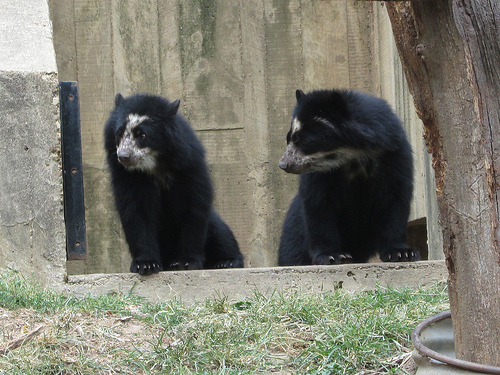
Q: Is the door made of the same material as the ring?
A: No, the door is made of wood and the ring is made of metal.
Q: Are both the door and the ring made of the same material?
A: No, the door is made of wood and the ring is made of metal.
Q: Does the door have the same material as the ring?
A: No, the door is made of wood and the ring is made of metal.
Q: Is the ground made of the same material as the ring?
A: No, the ground is made of concrete and the ring is made of metal.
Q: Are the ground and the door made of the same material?
A: No, the ground is made of cement and the door is made of wood.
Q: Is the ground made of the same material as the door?
A: No, the ground is made of cement and the door is made of wood.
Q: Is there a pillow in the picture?
A: No, there are no pillows.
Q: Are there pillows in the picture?
A: No, there are no pillows.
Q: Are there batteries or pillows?
A: No, there are no pillows or batteries.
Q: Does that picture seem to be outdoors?
A: Yes, the picture is outdoors.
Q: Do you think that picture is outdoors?
A: Yes, the picture is outdoors.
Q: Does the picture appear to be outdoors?
A: Yes, the picture is outdoors.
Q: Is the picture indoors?
A: No, the picture is outdoors.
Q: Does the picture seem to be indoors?
A: No, the picture is outdoors.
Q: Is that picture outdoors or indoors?
A: The picture is outdoors.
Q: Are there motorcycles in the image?
A: No, there are no motorcycles.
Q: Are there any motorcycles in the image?
A: No, there are no motorcycles.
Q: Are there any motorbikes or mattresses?
A: No, there are no motorbikes or mattresses.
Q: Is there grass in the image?
A: Yes, there is grass.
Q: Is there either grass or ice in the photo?
A: Yes, there is grass.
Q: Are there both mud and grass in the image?
A: No, there is grass but no mud.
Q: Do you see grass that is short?
A: Yes, there is short grass.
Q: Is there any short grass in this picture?
A: Yes, there is short grass.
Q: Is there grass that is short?
A: Yes, there is grass that is short.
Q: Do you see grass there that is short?
A: Yes, there is grass that is short.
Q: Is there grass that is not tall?
A: Yes, there is short grass.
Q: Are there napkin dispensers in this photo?
A: No, there are no napkin dispensers.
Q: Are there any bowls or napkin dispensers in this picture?
A: No, there are no napkin dispensers or bowls.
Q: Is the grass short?
A: Yes, the grass is short.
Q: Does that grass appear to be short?
A: Yes, the grass is short.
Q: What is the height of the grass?
A: The grass is short.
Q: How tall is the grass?
A: The grass is short.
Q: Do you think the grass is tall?
A: No, the grass is short.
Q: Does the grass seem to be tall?
A: No, the grass is short.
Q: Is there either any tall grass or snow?
A: No, there is grass but it is short.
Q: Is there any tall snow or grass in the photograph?
A: No, there is grass but it is short.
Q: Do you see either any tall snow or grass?
A: No, there is grass but it is short.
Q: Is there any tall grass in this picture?
A: No, there is grass but it is short.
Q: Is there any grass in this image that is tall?
A: No, there is grass but it is short.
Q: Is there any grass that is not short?
A: No, there is grass but it is short.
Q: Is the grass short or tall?
A: The grass is short.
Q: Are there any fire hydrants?
A: No, there are no fire hydrants.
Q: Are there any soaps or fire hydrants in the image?
A: No, there are no fire hydrants or soaps.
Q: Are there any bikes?
A: No, there are no bikes.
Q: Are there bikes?
A: No, there are no bikes.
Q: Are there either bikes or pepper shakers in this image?
A: No, there are no bikes or pepper shakers.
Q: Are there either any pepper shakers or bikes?
A: No, there are no bikes or pepper shakers.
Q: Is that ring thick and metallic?
A: Yes, the ring is thick and metallic.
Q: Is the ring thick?
A: Yes, the ring is thick.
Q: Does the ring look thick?
A: Yes, the ring is thick.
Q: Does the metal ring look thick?
A: Yes, the ring is thick.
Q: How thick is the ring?
A: The ring is thick.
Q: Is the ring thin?
A: No, the ring is thick.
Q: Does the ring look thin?
A: No, the ring is thick.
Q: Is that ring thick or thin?
A: The ring is thick.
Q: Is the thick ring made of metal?
A: Yes, the ring is made of metal.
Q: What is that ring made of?
A: The ring is made of metal.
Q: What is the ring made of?
A: The ring is made of metal.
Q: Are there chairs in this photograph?
A: No, there are no chairs.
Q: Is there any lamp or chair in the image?
A: No, there are no chairs or lamps.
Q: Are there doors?
A: Yes, there is a door.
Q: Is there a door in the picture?
A: Yes, there is a door.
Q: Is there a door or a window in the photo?
A: Yes, there is a door.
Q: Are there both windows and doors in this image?
A: No, there is a door but no windows.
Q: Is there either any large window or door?
A: Yes, there is a large door.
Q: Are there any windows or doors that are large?
A: Yes, the door is large.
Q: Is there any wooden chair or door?
A: Yes, there is a wood door.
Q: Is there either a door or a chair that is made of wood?
A: Yes, the door is made of wood.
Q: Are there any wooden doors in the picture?
A: Yes, there is a wood door.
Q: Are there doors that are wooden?
A: Yes, there is a door that is wooden.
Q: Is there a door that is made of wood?
A: Yes, there is a door that is made of wood.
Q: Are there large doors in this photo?
A: Yes, there is a large door.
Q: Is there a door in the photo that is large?
A: Yes, there is a door that is large.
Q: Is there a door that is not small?
A: Yes, there is a large door.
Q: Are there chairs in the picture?
A: No, there are no chairs.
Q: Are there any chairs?
A: No, there are no chairs.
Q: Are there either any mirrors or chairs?
A: No, there are no chairs or mirrors.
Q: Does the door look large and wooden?
A: Yes, the door is large and wooden.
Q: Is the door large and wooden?
A: Yes, the door is large and wooden.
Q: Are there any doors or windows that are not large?
A: No, there is a door but it is large.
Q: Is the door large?
A: Yes, the door is large.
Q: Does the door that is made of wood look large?
A: Yes, the door is large.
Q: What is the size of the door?
A: The door is large.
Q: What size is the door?
A: The door is large.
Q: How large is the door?
A: The door is large.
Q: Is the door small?
A: No, the door is large.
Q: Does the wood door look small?
A: No, the door is large.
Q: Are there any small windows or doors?
A: No, there is a door but it is large.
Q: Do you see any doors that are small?
A: No, there is a door but it is large.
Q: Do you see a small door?
A: No, there is a door but it is large.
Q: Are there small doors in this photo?
A: No, there is a door but it is large.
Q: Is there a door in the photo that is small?
A: No, there is a door but it is large.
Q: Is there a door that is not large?
A: No, there is a door but it is large.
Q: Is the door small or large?
A: The door is large.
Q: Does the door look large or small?
A: The door is large.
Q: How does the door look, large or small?
A: The door is large.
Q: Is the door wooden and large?
A: Yes, the door is wooden and large.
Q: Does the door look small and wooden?
A: No, the door is wooden but large.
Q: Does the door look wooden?
A: Yes, the door is wooden.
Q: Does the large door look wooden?
A: Yes, the door is wooden.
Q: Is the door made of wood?
A: Yes, the door is made of wood.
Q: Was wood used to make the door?
A: Yes, the door is made of wood.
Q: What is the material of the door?
A: The door is made of wood.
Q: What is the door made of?
A: The door is made of wood.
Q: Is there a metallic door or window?
A: No, there is a door but it is wooden.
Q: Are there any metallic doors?
A: No, there is a door but it is wooden.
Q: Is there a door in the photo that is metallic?
A: No, there is a door but it is wooden.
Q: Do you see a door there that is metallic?
A: No, there is a door but it is wooden.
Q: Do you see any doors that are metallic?
A: No, there is a door but it is wooden.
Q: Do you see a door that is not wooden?
A: No, there is a door but it is wooden.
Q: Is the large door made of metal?
A: No, the door is made of wood.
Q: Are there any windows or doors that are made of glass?
A: No, there is a door but it is made of wood.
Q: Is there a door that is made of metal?
A: No, there is a door but it is made of wood.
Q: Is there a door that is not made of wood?
A: No, there is a door but it is made of wood.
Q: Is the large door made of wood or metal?
A: The door is made of wood.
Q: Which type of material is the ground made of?
A: The ground is made of concrete.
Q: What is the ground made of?
A: The ground is made of concrete.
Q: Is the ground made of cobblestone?
A: No, the ground is made of concrete.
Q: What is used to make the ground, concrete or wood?
A: The ground is made of concrete.